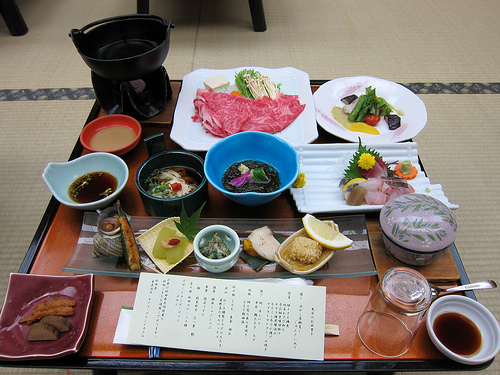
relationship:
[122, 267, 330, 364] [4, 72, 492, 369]
menu on table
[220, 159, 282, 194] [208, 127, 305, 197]
caviar in bowl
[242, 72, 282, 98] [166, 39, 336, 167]
mushrooms on plate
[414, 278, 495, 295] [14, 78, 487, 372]
spoon on tray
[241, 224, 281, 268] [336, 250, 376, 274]
food on glass dish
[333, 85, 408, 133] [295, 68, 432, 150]
vegetables on plate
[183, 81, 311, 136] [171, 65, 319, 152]
meat on plate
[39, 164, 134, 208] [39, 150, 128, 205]
sauce in bowl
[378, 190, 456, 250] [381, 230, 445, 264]
lid on dish